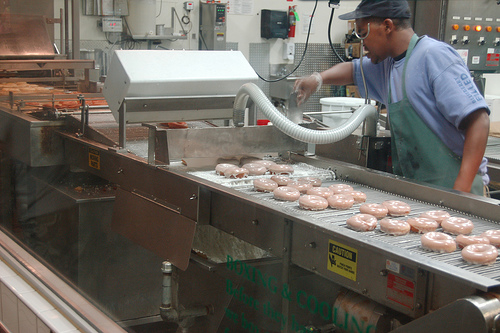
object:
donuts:
[456, 241, 500, 263]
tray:
[187, 157, 500, 283]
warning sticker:
[325, 238, 356, 283]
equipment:
[1, 1, 500, 332]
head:
[346, 3, 412, 63]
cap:
[334, 1, 413, 23]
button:
[449, 23, 460, 31]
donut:
[160, 118, 189, 130]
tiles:
[1, 254, 86, 333]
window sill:
[1, 227, 129, 333]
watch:
[311, 73, 321, 88]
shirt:
[345, 33, 491, 202]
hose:
[233, 82, 378, 145]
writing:
[294, 289, 307, 311]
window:
[2, 1, 500, 331]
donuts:
[1, 87, 21, 96]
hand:
[292, 71, 317, 107]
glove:
[289, 69, 322, 107]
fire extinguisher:
[286, 3, 296, 38]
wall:
[55, 1, 358, 124]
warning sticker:
[84, 147, 102, 171]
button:
[460, 23, 471, 34]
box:
[407, 3, 500, 75]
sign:
[383, 276, 416, 312]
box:
[257, 8, 290, 40]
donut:
[291, 192, 327, 213]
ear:
[379, 18, 395, 36]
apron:
[380, 31, 488, 199]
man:
[289, 0, 488, 196]